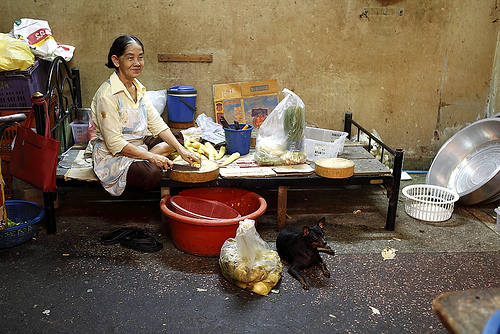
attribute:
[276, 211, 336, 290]
dog — little, black, brown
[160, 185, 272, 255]
basins — red, plastic, large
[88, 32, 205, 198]
woman — asian, smiling, darker, happy, sitting, preparing food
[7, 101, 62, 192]
purse — red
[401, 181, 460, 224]
basket — empty, white, slotted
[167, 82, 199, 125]
water jug — blue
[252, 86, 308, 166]
bag — plastic, tall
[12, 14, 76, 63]
bag — empty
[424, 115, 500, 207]
bowl — large, metal, round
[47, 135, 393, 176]
table — wooden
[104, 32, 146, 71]
hair — black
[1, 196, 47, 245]
container — round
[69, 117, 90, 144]
crate — plastic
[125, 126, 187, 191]
pants — brown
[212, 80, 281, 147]
oatmeal box — empty